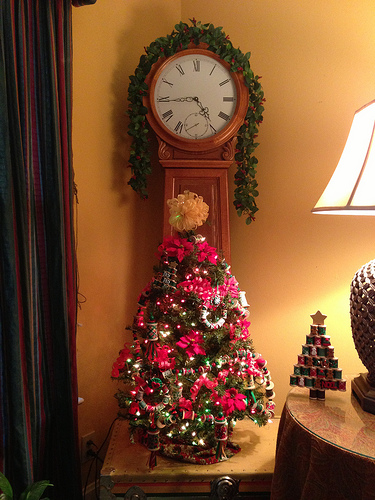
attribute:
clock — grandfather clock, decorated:
[145, 40, 247, 261]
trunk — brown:
[98, 412, 282, 498]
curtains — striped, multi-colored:
[1, 0, 85, 500]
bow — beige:
[166, 188, 211, 232]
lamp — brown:
[311, 96, 374, 414]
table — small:
[270, 373, 371, 499]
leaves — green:
[0, 472, 53, 499]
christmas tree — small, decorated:
[114, 190, 274, 466]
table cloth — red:
[276, 373, 375, 497]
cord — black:
[82, 449, 98, 499]